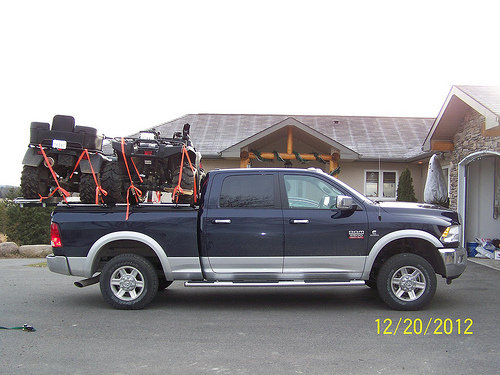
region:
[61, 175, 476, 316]
black truck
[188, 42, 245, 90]
white clouds in blue sky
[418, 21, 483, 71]
white clouds in blue sky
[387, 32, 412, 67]
white clouds in blue sky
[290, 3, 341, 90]
white clouds in blue sky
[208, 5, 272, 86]
white clouds in blue sky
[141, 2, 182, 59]
white clouds in blue sky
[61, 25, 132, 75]
white clouds in blue sky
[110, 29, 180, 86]
white clouds in blue sky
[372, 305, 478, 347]
Date the picture was taken.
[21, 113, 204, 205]
Four wheelers on the back of the truck.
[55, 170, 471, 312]
Dark blue pick up truck.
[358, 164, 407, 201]
Two windows in the building.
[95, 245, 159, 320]
Black tires on the truck.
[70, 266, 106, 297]
Long exhaust pipe on the truck.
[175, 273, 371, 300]
Running board on the truck.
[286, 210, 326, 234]
Silver door handle on the truck.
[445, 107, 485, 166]
Garage made from stones.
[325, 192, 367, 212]
Side mirror on the truck.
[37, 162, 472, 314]
a blue truck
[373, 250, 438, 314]
a wheel of truck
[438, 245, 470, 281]
a bumper of truck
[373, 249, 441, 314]
wheel of truck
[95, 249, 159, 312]
rear wheel of truck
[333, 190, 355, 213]
side mirror of truck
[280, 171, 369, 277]
door panel of truck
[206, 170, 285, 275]
door panel of truck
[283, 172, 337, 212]
a window of truck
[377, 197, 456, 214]
hood of truck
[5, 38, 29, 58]
white clouds in blue sky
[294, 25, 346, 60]
white clouds in blue sky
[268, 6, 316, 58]
white clouds in blue sky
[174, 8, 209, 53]
white clouds in blue sky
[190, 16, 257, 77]
white clouds in blue sky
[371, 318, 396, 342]
The numbers one and two next to eachother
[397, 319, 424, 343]
The numbers two and zero next to eachother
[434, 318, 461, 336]
The numbers two zero and one next to each other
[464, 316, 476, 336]
The last two seen on the time date stamp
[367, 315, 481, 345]
A time date stamp in the corner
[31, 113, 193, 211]
ATVS strapped into a truck bed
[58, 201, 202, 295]
The bed of the truck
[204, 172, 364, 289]
The cab of the truck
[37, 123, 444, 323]
A dark blue truck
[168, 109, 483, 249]
The house that is behind the truck